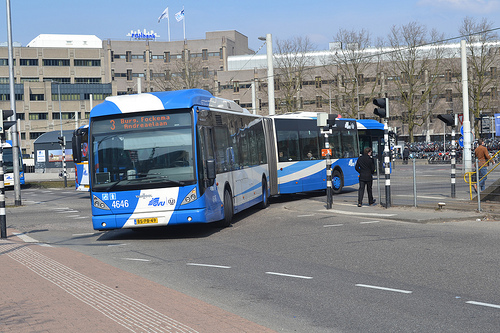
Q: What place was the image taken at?
A: It was taken at the road.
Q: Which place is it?
A: It is a road.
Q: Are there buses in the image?
A: Yes, there is a bus.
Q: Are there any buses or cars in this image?
A: Yes, there is a bus.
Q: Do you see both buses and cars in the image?
A: No, there is a bus but no cars.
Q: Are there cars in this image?
A: No, there are no cars.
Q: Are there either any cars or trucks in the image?
A: No, there are no cars or trucks.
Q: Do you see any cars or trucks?
A: No, there are no cars or trucks.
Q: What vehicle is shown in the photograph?
A: The vehicle is a bus.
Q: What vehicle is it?
A: The vehicle is a bus.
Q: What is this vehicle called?
A: That is a bus.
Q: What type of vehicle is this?
A: That is a bus.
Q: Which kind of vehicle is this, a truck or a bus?
A: That is a bus.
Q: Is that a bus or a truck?
A: That is a bus.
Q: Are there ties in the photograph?
A: No, there are no ties.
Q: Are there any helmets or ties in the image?
A: No, there are no ties or helmets.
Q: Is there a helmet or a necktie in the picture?
A: No, there are no ties or helmets.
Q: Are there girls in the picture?
A: No, there are no girls.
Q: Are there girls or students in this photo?
A: No, there are no girls or students.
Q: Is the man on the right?
A: Yes, the man is on the right of the image.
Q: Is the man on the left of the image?
A: No, the man is on the right of the image.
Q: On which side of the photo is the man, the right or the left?
A: The man is on the right of the image.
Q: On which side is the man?
A: The man is on the right of the image.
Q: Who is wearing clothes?
A: The man is wearing clothes.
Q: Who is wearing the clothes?
A: The man is wearing clothes.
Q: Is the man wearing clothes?
A: Yes, the man is wearing clothes.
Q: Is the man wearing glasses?
A: No, the man is wearing clothes.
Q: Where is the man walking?
A: The man is walking on the road.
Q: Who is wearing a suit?
A: The man is wearing a suit.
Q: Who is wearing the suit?
A: The man is wearing a suit.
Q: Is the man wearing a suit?
A: Yes, the man is wearing a suit.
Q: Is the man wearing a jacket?
A: No, the man is wearing a suit.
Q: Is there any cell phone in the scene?
A: No, there are no cell phones.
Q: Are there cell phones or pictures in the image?
A: No, there are no cell phones or pictures.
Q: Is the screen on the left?
A: Yes, the screen is on the left of the image.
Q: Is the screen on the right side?
A: No, the screen is on the left of the image.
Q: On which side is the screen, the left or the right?
A: The screen is on the left of the image.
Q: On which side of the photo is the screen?
A: The screen is on the left of the image.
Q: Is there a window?
A: Yes, there are windows.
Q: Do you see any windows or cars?
A: Yes, there are windows.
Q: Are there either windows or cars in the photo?
A: Yes, there are windows.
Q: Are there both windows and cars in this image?
A: No, there are windows but no cars.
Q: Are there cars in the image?
A: No, there are no cars.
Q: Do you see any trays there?
A: No, there are no trays.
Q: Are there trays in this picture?
A: No, there are no trays.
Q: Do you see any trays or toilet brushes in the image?
A: No, there are no trays or toilet brushes.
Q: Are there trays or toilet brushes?
A: No, there are no trays or toilet brushes.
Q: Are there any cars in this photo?
A: No, there are no cars.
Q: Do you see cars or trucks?
A: No, there are no cars or trucks.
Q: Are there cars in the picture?
A: No, there are no cars.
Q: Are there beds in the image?
A: No, there are no beds.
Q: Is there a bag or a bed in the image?
A: No, there are no beds or bags.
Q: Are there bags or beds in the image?
A: No, there are no beds or bags.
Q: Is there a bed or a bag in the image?
A: No, there are no beds or bags.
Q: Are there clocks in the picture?
A: No, there are no clocks.